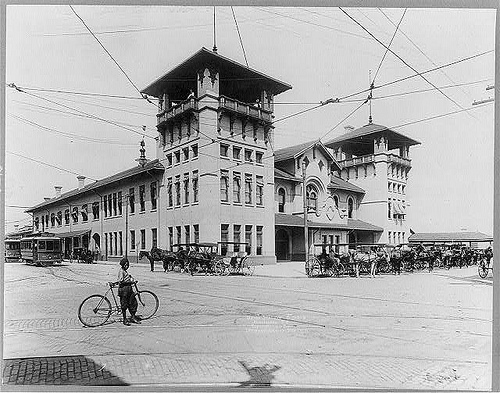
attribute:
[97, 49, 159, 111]
wire — black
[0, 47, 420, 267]
building — tall, old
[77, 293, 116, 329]
wheel — large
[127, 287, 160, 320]
wheel — large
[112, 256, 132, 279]
skin — dark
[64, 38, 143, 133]
sky — gloomy, grey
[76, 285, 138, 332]
bicycle — old style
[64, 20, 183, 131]
wire — black